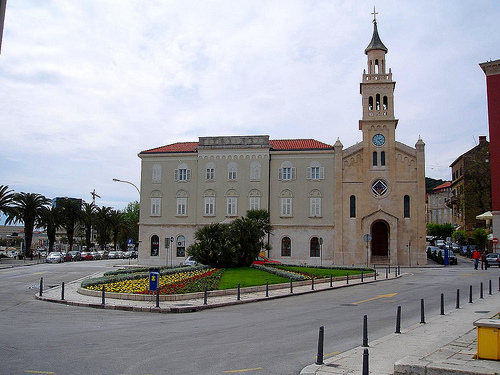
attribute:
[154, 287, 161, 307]
post — black, grey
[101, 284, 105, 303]
post — black, grey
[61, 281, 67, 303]
post — black, grey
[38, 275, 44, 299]
post — black, grey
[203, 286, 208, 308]
post — black, grey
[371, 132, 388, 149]
clock — blue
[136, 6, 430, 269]
building — brown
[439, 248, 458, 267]
car — parked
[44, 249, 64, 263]
car — parked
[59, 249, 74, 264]
car — parked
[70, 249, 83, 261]
car — parked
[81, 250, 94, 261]
car — parked, red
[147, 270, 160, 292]
sign — blue, yellow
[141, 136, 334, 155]
roof — red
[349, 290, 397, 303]
arrow — yellow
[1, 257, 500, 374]
street — paved, grey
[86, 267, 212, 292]
flowers — yellow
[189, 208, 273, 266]
bush — large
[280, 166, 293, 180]
window — arched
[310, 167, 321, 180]
window — arched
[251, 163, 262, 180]
window — arched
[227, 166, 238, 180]
window — arched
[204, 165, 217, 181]
window — arched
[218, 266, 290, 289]
grass — well manicured, green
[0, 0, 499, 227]
sky — white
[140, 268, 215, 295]
flowers — red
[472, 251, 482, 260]
shirt — red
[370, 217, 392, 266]
door — archway